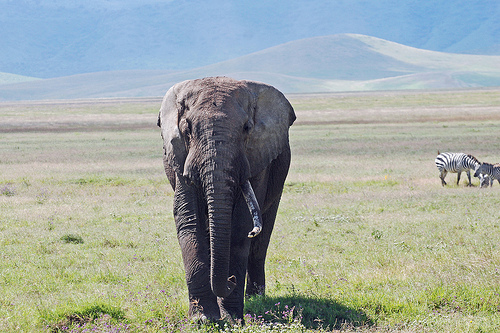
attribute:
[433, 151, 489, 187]
zebras — grazing, together, black, white, standing, eating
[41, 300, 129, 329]
grass — green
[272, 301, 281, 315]
flowers — tiny, purple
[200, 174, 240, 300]
trunk — long, gray, curled, upward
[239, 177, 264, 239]
tusk — old, white, dirty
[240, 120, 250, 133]
eyes — open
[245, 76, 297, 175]
ear — floppy, big, gray, large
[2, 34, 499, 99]
dune — large, sand, in distance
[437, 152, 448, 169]
stripes — black, white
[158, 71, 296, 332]
elephant — walking, large, standing, grey, gray, wrinkled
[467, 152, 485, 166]
mane — black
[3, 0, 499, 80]
mountains — rolling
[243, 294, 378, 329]
shadow — cast